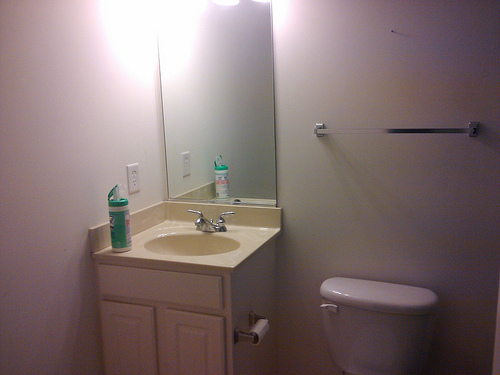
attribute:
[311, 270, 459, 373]
toilet — white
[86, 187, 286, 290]
sink — tan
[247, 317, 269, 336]
toilet paper — silver, white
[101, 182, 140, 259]
wipes — green, white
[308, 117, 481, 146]
towel rack — silver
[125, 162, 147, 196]
outlet — beige, white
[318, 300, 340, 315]
handle — white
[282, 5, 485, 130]
wall — white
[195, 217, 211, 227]
faucet — metal, silver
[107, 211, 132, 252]
container — green, white